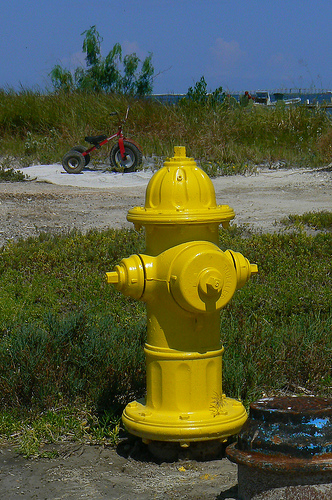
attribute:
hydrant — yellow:
[106, 146, 262, 448]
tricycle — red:
[62, 111, 143, 172]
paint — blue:
[256, 408, 329, 451]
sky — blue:
[236, 8, 326, 69]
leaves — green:
[85, 43, 97, 58]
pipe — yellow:
[135, 309, 230, 406]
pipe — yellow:
[138, 301, 228, 409]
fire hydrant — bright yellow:
[96, 140, 263, 461]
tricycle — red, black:
[55, 101, 146, 179]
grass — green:
[21, 271, 91, 376]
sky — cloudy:
[1, 2, 330, 91]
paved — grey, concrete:
[5, 447, 240, 498]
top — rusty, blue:
[220, 393, 331, 473]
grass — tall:
[3, 85, 331, 165]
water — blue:
[154, 90, 191, 96]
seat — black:
[80, 130, 108, 145]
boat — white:
[249, 89, 306, 104]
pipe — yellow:
[99, 254, 150, 302]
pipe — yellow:
[164, 238, 241, 320]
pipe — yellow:
[218, 242, 262, 291]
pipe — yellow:
[98, 249, 159, 302]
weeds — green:
[0, 306, 147, 420]